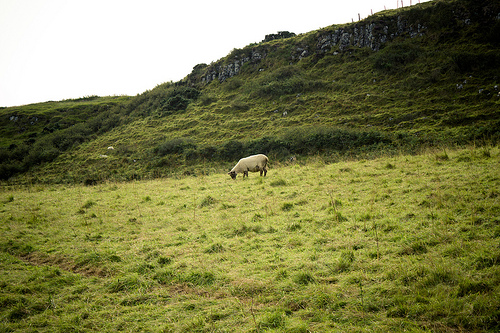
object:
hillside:
[1, 4, 498, 151]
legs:
[243, 170, 249, 182]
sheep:
[224, 151, 272, 186]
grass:
[35, 3, 499, 179]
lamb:
[228, 151, 271, 181]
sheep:
[105, 141, 117, 153]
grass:
[22, 172, 483, 330]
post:
[357, 11, 362, 21]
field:
[16, 188, 498, 299]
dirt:
[9, 250, 112, 282]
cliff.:
[324, 17, 440, 61]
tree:
[263, 28, 297, 41]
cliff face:
[185, 0, 497, 104]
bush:
[261, 27, 306, 42]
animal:
[230, 154, 271, 181]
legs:
[260, 167, 262, 178]